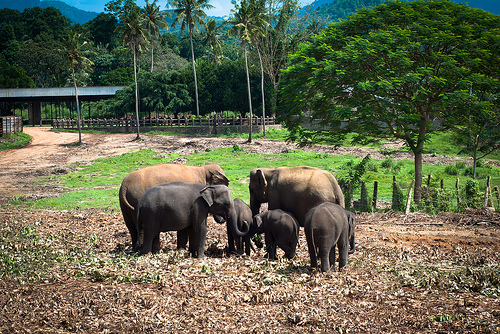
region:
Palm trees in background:
[55, 0, 284, 132]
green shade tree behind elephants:
[276, 0, 496, 195]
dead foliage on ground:
[21, 254, 498, 333]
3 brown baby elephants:
[218, 194, 365, 264]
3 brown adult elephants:
[116, 151, 347, 251]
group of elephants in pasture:
[109, 157, 362, 271]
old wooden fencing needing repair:
[349, 157, 499, 219]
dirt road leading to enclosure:
[3, 120, 95, 205]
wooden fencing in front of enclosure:
[4, 111, 280, 138]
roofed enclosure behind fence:
[1, 79, 138, 127]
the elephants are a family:
[114, 152, 363, 279]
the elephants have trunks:
[119, 146, 358, 283]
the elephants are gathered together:
[106, 152, 370, 285]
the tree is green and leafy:
[277, 2, 499, 221]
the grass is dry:
[3, 178, 495, 332]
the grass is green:
[2, 121, 499, 252]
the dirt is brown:
[3, 120, 499, 224]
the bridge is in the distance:
[1, 80, 151, 127]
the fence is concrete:
[43, 113, 303, 140]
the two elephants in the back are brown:
[109, 155, 354, 240]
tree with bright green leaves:
[360, 1, 495, 223]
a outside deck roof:
[0, 80, 139, 115]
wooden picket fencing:
[47, 108, 282, 132]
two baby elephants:
[225, 200, 299, 263]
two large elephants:
[114, 125, 233, 294]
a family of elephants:
[227, 149, 365, 282]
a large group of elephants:
[70, 131, 415, 310]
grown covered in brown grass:
[0, 264, 475, 325]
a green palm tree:
[109, 3, 156, 148]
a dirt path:
[0, 111, 85, 231]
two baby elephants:
[218, 192, 305, 259]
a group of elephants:
[103, 136, 394, 302]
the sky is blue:
[3, 2, 326, 44]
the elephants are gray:
[100, 146, 369, 279]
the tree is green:
[268, 11, 498, 233]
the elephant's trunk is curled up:
[203, 186, 257, 249]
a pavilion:
[0, 71, 147, 150]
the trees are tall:
[53, 2, 340, 160]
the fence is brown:
[43, 111, 284, 135]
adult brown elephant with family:
[244, 168, 296, 193]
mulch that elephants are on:
[65, 250, 195, 314]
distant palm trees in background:
[63, 56, 99, 83]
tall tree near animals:
[332, 75, 432, 130]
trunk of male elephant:
[224, 202, 259, 235]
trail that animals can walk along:
[24, 90, 71, 146]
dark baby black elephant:
[263, 208, 298, 256]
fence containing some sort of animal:
[156, 113, 215, 132]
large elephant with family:
[113, 157, 217, 202]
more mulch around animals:
[391, 214, 466, 247]